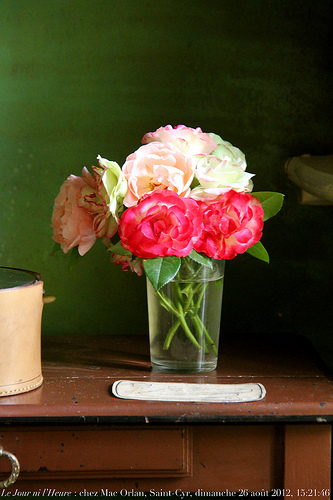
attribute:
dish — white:
[112, 379, 264, 403]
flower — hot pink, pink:
[200, 189, 262, 261]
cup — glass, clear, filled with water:
[145, 253, 224, 371]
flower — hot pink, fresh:
[121, 189, 204, 258]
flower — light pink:
[127, 145, 194, 208]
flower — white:
[198, 133, 256, 194]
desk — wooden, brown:
[2, 329, 331, 497]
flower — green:
[87, 159, 127, 243]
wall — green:
[1, 1, 332, 334]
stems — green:
[151, 285, 217, 355]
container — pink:
[1, 267, 42, 399]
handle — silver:
[0, 450, 21, 489]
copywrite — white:
[2, 483, 330, 495]